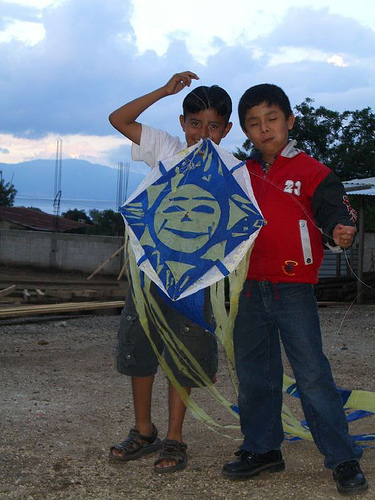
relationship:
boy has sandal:
[107, 71, 234, 477] [110, 426, 164, 466]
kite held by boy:
[117, 135, 269, 303] [107, 71, 234, 477]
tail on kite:
[119, 233, 239, 441] [117, 135, 269, 303]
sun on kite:
[136, 161, 252, 286] [117, 135, 269, 303]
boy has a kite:
[107, 71, 234, 477] [117, 135, 269, 303]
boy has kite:
[107, 71, 234, 477] [117, 135, 269, 303]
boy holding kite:
[107, 71, 234, 477] [117, 135, 269, 303]